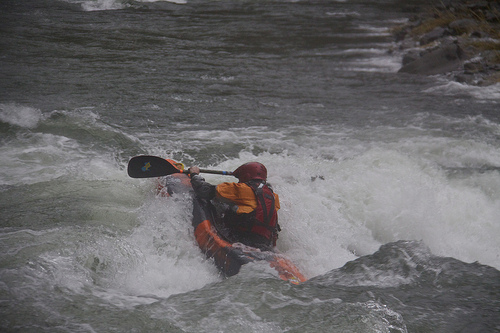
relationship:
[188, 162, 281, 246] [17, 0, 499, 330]
man kayaking in water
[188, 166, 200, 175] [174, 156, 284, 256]
hand of person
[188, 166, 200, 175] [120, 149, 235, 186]
hand holding paddle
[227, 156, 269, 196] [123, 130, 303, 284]
hat on kayaker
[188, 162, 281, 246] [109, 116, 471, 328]
man paddling in waves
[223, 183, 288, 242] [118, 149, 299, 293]
vest on boarder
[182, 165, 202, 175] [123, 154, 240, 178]
hand on paddle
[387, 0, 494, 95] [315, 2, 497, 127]
rocks on shoreline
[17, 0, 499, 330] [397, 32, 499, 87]
water on rock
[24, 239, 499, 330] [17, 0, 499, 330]
rock in water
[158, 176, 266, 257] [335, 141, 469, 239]
canoe in waters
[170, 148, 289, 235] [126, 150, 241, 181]
man holding paddle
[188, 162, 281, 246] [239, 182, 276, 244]
man wearing life vest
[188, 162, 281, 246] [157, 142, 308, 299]
man in canoe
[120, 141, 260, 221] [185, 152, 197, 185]
oar on hand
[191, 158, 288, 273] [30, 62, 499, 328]
kayaker in water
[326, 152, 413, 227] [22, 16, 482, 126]
waves in river